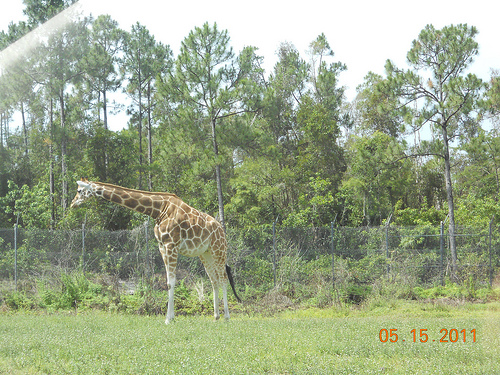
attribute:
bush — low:
[4, 272, 36, 308]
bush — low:
[34, 270, 61, 308]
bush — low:
[50, 266, 82, 310]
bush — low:
[337, 260, 375, 308]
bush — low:
[409, 274, 465, 305]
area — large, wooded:
[7, 58, 477, 260]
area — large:
[71, 15, 469, 265]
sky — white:
[153, 4, 463, 51]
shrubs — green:
[266, 255, 415, 290]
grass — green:
[89, 316, 390, 359]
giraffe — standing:
[68, 180, 231, 320]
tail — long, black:
[223, 261, 243, 306]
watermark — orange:
[372, 326, 479, 347]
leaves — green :
[356, 143, 383, 168]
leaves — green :
[372, 179, 391, 195]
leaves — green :
[365, 167, 393, 187]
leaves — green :
[361, 168, 376, 195]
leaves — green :
[366, 157, 392, 187]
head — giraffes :
[66, 171, 111, 214]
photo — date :
[373, 321, 483, 341]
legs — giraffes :
[156, 248, 250, 334]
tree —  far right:
[320, 117, 433, 291]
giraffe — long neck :
[67, 173, 173, 217]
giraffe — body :
[149, 185, 243, 270]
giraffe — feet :
[54, 173, 247, 318]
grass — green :
[44, 317, 460, 363]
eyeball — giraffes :
[73, 186, 93, 194]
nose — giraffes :
[69, 197, 95, 213]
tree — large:
[153, 20, 281, 230]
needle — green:
[229, 46, 233, 54]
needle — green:
[227, 36, 230, 44]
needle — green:
[204, 23, 206, 29]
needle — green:
[194, 52, 195, 54]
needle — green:
[183, 89, 186, 91]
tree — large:
[370, 19, 483, 269]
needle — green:
[471, 44, 474, 50]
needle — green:
[452, 35, 455, 41]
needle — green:
[413, 40, 415, 45]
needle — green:
[407, 56, 410, 61]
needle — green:
[443, 84, 444, 89]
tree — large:
[82, 12, 129, 181]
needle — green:
[100, 16, 101, 20]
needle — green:
[114, 22, 115, 25]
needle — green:
[105, 14, 106, 18]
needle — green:
[96, 34, 97, 38]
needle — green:
[108, 22, 110, 27]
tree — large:
[350, 127, 416, 236]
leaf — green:
[364, 140, 367, 145]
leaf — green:
[380, 137, 381, 140]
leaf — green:
[374, 130, 376, 133]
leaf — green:
[367, 153, 369, 157]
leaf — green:
[401, 161, 404, 166]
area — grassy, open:
[1, 304, 483, 371]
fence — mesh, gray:
[1, 216, 484, 291]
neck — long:
[90, 180, 174, 221]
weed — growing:
[32, 272, 46, 303]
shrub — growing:
[52, 260, 88, 311]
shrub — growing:
[82, 274, 104, 308]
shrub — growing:
[122, 276, 152, 314]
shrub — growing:
[6, 275, 26, 308]